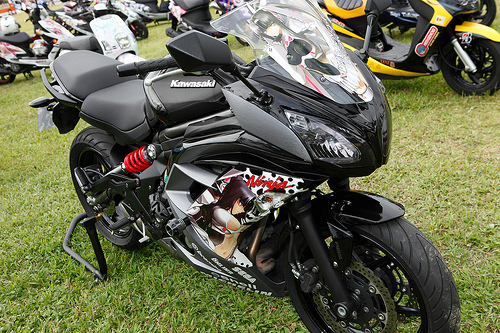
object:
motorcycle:
[29, 0, 462, 333]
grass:
[0, 101, 499, 329]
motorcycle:
[322, 1, 499, 95]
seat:
[55, 52, 160, 145]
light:
[281, 109, 359, 165]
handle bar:
[116, 44, 244, 77]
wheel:
[283, 200, 462, 332]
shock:
[122, 145, 152, 173]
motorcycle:
[0, 12, 97, 87]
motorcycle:
[172, 1, 228, 37]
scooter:
[67, 1, 147, 40]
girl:
[248, 9, 368, 105]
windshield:
[211, 1, 373, 106]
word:
[245, 173, 295, 192]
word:
[169, 79, 215, 88]